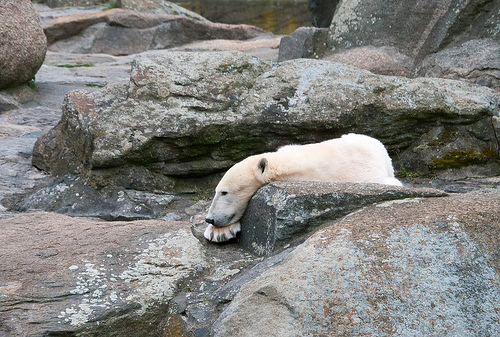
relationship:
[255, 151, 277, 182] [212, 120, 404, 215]
ear of bear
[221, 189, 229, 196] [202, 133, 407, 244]
eye of bear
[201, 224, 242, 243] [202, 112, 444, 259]
claw of bear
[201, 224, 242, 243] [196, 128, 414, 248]
claw of polar bear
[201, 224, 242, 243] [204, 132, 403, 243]
claw of polar bear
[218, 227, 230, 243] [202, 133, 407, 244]
claw of bear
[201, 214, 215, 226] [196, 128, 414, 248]
nose of polar bear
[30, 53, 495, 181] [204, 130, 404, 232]
large rock behind polar bear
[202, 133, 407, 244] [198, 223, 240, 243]
bear has leg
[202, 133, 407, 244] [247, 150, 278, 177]
bear has ear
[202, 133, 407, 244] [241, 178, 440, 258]
bear between rock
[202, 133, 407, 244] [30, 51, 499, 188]
bear between large rock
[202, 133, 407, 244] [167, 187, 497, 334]
bear between rock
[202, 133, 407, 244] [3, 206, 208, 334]
bear between rock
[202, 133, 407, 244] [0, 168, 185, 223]
bear between rock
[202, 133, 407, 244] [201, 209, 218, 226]
bear has nose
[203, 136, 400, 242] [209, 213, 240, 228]
bear has mouth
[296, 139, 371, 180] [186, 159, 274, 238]
loin on bear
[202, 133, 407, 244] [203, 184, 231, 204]
bear has eyes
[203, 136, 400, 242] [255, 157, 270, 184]
bear has ear